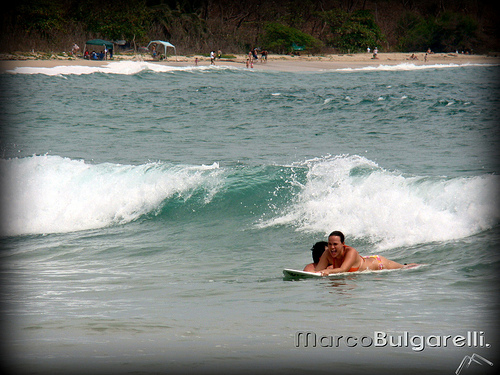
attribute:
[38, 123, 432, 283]
wave — white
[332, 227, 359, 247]
hair — brown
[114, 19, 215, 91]
tent — green , small 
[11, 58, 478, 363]
water — wavy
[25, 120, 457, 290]
wave — Big 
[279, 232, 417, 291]
woman — surfing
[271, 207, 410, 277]
woman — surfing, laying down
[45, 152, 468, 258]
waves — crashing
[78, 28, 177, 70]
tents — set up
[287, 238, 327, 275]
person — helping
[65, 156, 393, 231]
waves — splashing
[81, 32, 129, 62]
canopy — green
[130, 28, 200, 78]
canopy — white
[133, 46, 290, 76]
people — distant